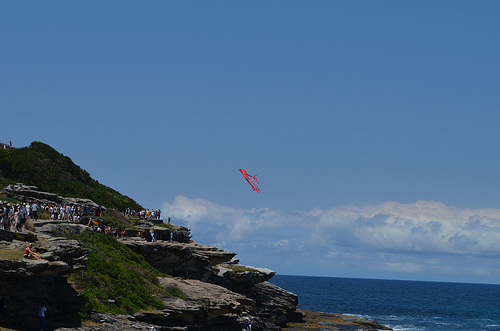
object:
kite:
[234, 166, 263, 194]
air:
[293, 137, 476, 265]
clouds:
[155, 194, 498, 280]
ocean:
[261, 274, 498, 331]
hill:
[0, 140, 296, 330]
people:
[146, 228, 155, 245]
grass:
[70, 228, 190, 321]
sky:
[0, 0, 499, 285]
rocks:
[206, 259, 275, 288]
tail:
[246, 175, 259, 193]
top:
[23, 139, 62, 150]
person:
[22, 241, 43, 262]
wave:
[271, 274, 499, 331]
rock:
[24, 257, 53, 273]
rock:
[65, 319, 182, 331]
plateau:
[284, 312, 393, 331]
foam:
[340, 313, 499, 331]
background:
[0, 0, 499, 331]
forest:
[0, 138, 144, 210]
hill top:
[0, 141, 153, 216]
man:
[35, 301, 51, 322]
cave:
[1, 264, 87, 331]